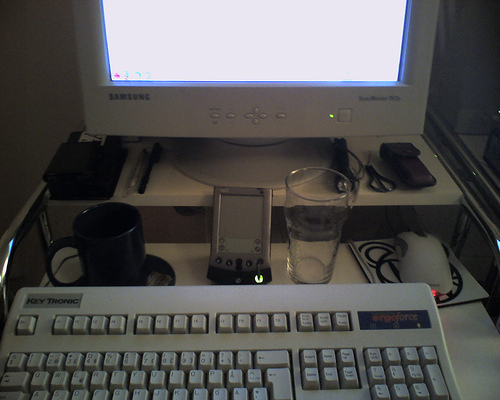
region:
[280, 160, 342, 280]
empty glass on desk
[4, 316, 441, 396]
white keyboard for computer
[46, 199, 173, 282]
black coffee mug sitting to the right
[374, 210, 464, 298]
mouse for keypad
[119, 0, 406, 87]
moniter screen is blank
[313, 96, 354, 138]
green light is on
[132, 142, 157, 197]
two pens on the desk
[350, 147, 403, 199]
scissors are black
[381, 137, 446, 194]
case is to the left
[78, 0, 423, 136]
moniter is a samsung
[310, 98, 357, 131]
green light on the computer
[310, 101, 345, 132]
the power button is lit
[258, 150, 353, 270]
an empty glass cup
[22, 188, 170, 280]
a black coffee mug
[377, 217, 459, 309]
the mouse is white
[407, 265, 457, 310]
red light on the mouse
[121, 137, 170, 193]
pens under the computer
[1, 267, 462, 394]
the keyboard is off white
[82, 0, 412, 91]
the screen is white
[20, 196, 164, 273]
the cup is empty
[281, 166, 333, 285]
the glass is empty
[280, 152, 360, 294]
the glass is empty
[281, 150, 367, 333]
the glass is empty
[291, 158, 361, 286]
the glass is empty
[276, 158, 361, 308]
the glass is empty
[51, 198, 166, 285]
the mug is black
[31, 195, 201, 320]
the mug is black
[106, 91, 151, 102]
Samsung in black text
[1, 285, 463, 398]
a gray computer keyboard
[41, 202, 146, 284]
a black ceramic coffee mug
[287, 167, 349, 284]
a clear water glass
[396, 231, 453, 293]
a two toned gray mouse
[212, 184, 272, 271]
a gray personal digital assistant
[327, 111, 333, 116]
a green power light on a monitor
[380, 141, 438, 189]
a brown leatherman case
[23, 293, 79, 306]
Key Tronic on a keyboard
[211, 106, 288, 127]
buttons on the front of a monitor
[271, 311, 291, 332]
key on the laptop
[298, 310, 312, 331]
key on the laptop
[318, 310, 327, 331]
key on the laptop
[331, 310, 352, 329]
key on the laptop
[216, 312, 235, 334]
key on the laptop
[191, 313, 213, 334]
key on the laptop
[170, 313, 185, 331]
key on the laptop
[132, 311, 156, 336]
key on the laptop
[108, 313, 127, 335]
key on the laptop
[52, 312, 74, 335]
key on the laptop